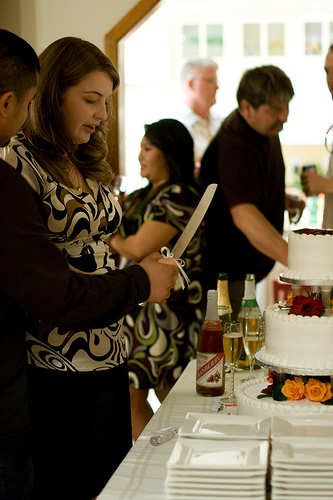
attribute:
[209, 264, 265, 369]
champagne — opened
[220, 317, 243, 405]
champagne glass — several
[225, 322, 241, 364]
glass — champagne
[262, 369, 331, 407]
flowers — decorative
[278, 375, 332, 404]
roses — yellow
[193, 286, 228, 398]
bottle — closed, cranberry, unopened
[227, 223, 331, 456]
cake — white, three-tier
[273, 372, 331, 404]
roses — beautiful, yellow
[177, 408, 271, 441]
plate — white, stacked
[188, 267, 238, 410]
glass — wine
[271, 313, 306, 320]
frosting — white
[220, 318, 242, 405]
glass — tall, champagne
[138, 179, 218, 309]
cake knife — large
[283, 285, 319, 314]
floewr — red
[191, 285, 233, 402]
bottle — red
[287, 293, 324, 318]
flower — red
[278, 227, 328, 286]
cake — three tiered, white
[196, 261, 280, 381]
bottles — open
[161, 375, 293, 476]
plate — white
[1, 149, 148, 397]
shirt — long sleeve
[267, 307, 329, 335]
frosting — white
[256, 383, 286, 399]
leaves — green